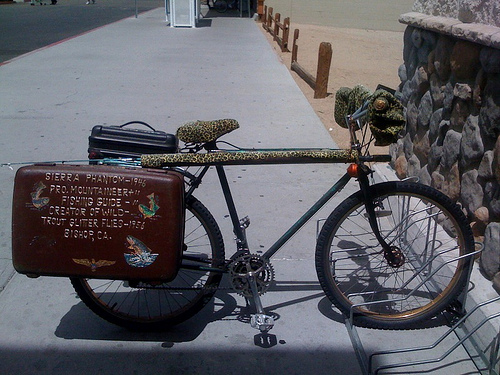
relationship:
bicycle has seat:
[64, 98, 470, 330] [177, 119, 239, 145]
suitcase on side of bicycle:
[11, 163, 184, 286] [64, 98, 470, 330]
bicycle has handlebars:
[64, 98, 470, 330] [338, 84, 403, 120]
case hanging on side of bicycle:
[87, 125, 178, 159] [64, 98, 470, 330]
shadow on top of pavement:
[212, 277, 235, 316] [241, 188, 302, 216]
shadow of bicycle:
[212, 277, 235, 316] [64, 98, 470, 330]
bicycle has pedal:
[64, 98, 470, 330] [252, 313, 277, 334]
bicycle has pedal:
[64, 98, 470, 330] [238, 216, 251, 229]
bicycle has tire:
[64, 98, 470, 330] [315, 182, 475, 327]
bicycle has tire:
[64, 98, 470, 330] [69, 277, 228, 330]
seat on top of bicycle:
[177, 119, 239, 145] [64, 98, 470, 330]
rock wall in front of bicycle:
[412, 44, 500, 170] [64, 98, 470, 330]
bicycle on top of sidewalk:
[64, 98, 470, 330] [83, 37, 282, 113]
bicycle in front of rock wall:
[64, 98, 470, 330] [412, 44, 500, 170]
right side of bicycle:
[152, 159, 427, 287] [64, 98, 470, 330]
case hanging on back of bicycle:
[87, 125, 178, 159] [64, 98, 470, 330]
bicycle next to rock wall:
[64, 98, 470, 330] [412, 44, 500, 170]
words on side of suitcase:
[50, 173, 132, 240] [11, 163, 184, 286]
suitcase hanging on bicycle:
[11, 163, 184, 286] [64, 98, 470, 330]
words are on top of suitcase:
[50, 173, 132, 240] [11, 163, 184, 286]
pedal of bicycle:
[252, 313, 277, 334] [64, 98, 470, 330]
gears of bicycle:
[184, 248, 272, 298] [64, 98, 470, 330]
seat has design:
[177, 119, 239, 145] [186, 125, 207, 140]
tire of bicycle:
[315, 182, 475, 327] [64, 98, 470, 330]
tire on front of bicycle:
[315, 182, 475, 327] [64, 98, 470, 330]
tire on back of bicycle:
[69, 277, 228, 330] [64, 98, 470, 330]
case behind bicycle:
[87, 125, 178, 159] [64, 98, 470, 330]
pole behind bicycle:
[316, 43, 334, 100] [64, 98, 470, 330]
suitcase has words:
[11, 163, 184, 286] [50, 173, 132, 240]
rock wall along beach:
[412, 44, 500, 170] [344, 28, 396, 82]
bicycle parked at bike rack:
[64, 98, 470, 330] [352, 203, 499, 374]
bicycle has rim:
[64, 98, 470, 330] [360, 306, 422, 320]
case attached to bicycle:
[87, 125, 178, 159] [64, 98, 470, 330]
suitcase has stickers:
[11, 163, 184, 286] [123, 234, 159, 272]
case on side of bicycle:
[87, 125, 178, 159] [64, 98, 470, 330]